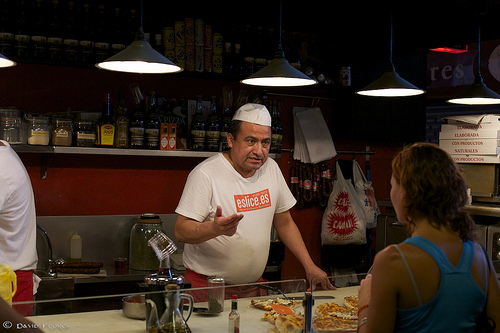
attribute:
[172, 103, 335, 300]
man — looking, gesturing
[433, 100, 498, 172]
boxes — stacked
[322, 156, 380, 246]
bags — plastic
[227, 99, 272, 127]
hat — white, paper, small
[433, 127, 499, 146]
boxes — stacked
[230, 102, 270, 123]
hat — white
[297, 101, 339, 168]
sheet — hanging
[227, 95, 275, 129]
hat — white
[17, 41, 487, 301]
restaurant — open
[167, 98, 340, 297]
pizza man — talking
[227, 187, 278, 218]
symbol — white, orange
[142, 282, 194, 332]
bottle — glass, clear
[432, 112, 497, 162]
boxes — filled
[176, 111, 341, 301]
owner — chatting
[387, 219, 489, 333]
tank — blue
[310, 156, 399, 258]
bags — white